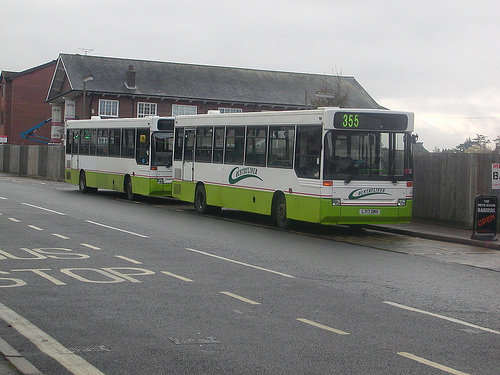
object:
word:
[99, 265, 155, 283]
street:
[1, 176, 499, 375]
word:
[40, 246, 87, 258]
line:
[20, 200, 66, 218]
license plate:
[358, 207, 381, 216]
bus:
[170, 106, 415, 228]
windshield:
[320, 129, 413, 183]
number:
[341, 113, 349, 126]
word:
[475, 219, 483, 228]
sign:
[470, 195, 499, 238]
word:
[491, 204, 496, 210]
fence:
[415, 151, 499, 227]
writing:
[236, 169, 242, 177]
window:
[97, 98, 120, 119]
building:
[1, 53, 393, 180]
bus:
[64, 114, 173, 200]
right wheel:
[273, 194, 290, 231]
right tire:
[193, 184, 207, 212]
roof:
[49, 52, 387, 111]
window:
[134, 101, 158, 119]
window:
[171, 102, 197, 117]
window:
[218, 106, 242, 115]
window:
[63, 100, 77, 118]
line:
[84, 218, 148, 240]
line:
[184, 246, 296, 283]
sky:
[1, 2, 500, 153]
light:
[330, 197, 340, 205]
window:
[265, 125, 297, 171]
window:
[295, 123, 320, 179]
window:
[222, 125, 248, 167]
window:
[210, 126, 227, 166]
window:
[193, 126, 214, 165]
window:
[119, 127, 137, 158]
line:
[116, 254, 144, 266]